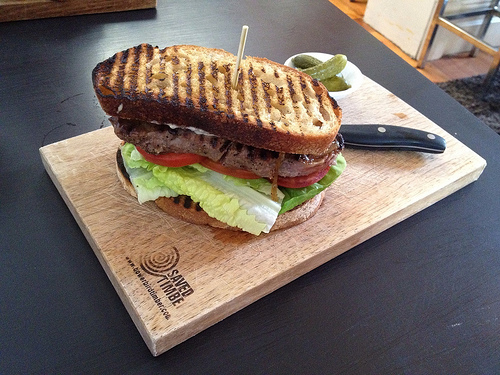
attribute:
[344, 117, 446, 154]
handle — black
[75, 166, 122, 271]
board — wood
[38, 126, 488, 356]
cutting board — wooden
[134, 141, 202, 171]
tomato — sliced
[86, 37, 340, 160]
bread — toasted, grilled, white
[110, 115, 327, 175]
steak — cooked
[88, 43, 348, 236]
sandwich — tall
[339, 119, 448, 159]
utensil handle — black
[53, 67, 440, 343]
chopping board — beige, white, rectangular, wooden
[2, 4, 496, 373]
table — wooden, black